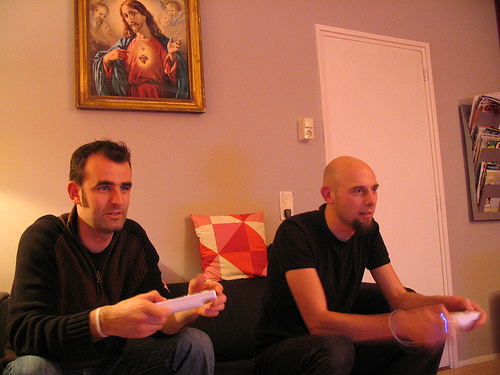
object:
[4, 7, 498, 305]
wall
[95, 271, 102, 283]
zipper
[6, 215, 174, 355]
sweater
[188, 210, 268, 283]
pillow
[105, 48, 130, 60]
hand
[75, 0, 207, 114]
picture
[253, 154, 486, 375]
man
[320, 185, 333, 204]
ear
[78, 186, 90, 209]
side burn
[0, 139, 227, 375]
man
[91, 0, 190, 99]
jesus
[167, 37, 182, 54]
hand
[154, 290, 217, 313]
wii controller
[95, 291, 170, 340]
hand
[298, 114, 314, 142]
thermostat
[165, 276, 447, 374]
couch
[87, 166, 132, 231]
face